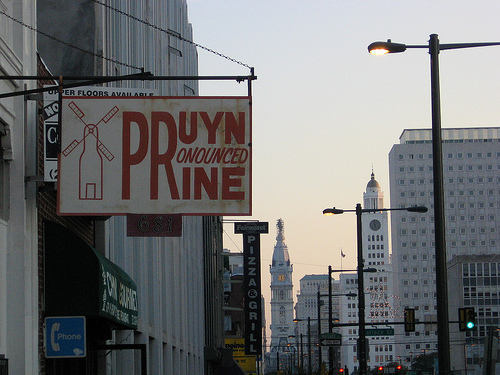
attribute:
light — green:
[465, 322, 472, 329]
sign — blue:
[41, 313, 88, 360]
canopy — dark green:
[36, 226, 144, 333]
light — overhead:
[285, 339, 292, 349]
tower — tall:
[255, 210, 353, 361]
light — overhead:
[381, 19, 478, 354]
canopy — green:
[44, 218, 141, 332]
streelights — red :
[336, 363, 423, 373]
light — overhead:
[319, 198, 430, 219]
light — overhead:
[363, 28, 428, 68]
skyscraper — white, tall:
[384, 124, 498, 369]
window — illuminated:
[274, 273, 288, 283]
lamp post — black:
[362, 30, 499, 374]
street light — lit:
[367, 40, 406, 57]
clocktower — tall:
[348, 170, 397, 357]